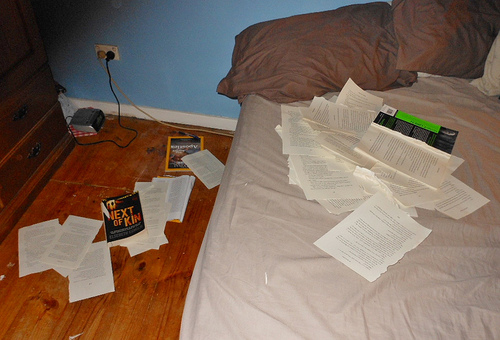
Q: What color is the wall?
A: Blue.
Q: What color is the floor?
A: Brown.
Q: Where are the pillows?
A: On the bed.